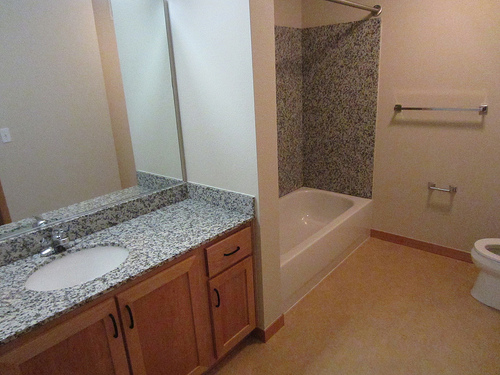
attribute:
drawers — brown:
[116, 289, 261, 370]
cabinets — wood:
[3, 221, 260, 373]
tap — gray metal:
[40, 227, 77, 257]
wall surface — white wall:
[169, 0, 266, 334]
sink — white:
[24, 244, 129, 291]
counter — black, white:
[7, 192, 241, 279]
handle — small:
[425, 177, 459, 199]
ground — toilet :
[442, 187, 468, 204]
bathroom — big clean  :
[38, 26, 495, 368]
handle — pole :
[391, 93, 495, 124]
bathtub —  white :
[272, 188, 375, 308]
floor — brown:
[213, 234, 496, 372]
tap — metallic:
[38, 231, 80, 257]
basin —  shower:
[279, 183, 376, 320]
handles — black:
[103, 310, 120, 337]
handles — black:
[121, 303, 139, 326]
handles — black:
[210, 288, 222, 307]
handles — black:
[221, 243, 241, 257]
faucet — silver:
[29, 195, 86, 277]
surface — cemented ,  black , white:
[142, 185, 197, 239]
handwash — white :
[5, 259, 21, 271]